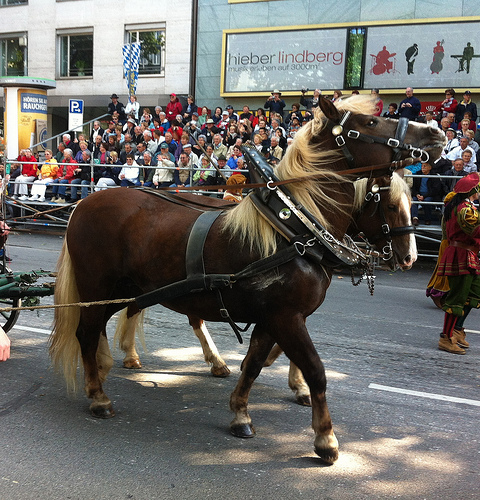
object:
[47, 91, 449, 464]
horse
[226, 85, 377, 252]
blond mane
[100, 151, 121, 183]
spectators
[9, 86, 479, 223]
crowd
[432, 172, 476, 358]
man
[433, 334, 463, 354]
boots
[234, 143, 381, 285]
bridle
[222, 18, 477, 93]
advertisement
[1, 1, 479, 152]
building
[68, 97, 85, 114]
parking sign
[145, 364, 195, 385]
sunlight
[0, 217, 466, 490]
asphalt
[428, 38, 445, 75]
picture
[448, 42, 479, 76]
musicians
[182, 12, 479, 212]
store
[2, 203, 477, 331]
parade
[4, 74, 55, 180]
advertisement tower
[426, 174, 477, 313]
costume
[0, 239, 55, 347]
cart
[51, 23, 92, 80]
window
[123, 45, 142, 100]
flag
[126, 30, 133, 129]
pole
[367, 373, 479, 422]
line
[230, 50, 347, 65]
hieber lindberg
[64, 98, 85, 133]
park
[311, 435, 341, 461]
hooves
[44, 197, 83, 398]
tail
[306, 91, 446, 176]
head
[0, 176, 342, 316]
reigns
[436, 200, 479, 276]
coat